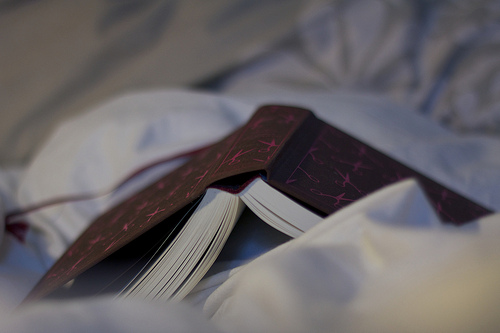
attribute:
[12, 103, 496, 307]
book — big, facing down, brown, open, opened, face down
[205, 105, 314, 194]
spine — dark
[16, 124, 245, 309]
front cover — dark red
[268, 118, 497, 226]
back cover — dark red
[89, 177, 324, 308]
pages — white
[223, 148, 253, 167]
scissors — pink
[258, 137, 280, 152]
scissors — pink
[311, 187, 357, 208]
scissors — pink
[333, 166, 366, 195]
scissors — pink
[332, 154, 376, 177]
scissors — pink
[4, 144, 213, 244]
bookmark — red, satin, dark red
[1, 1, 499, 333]
fabric — white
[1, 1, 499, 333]
sheet — white